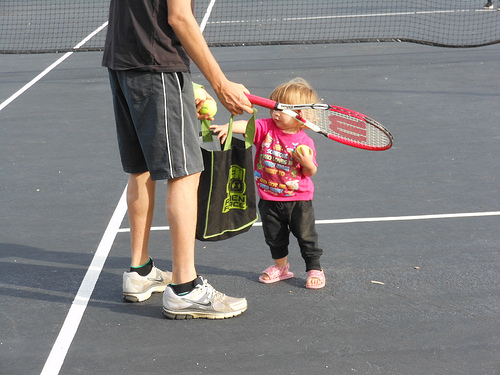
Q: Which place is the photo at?
A: It is at the field.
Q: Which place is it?
A: It is a field.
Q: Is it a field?
A: Yes, it is a field.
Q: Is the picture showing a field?
A: Yes, it is showing a field.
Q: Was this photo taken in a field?
A: Yes, it was taken in a field.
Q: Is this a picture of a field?
A: Yes, it is showing a field.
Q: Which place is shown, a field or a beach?
A: It is a field.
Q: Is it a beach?
A: No, it is a field.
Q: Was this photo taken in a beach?
A: No, the picture was taken in a field.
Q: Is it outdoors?
A: Yes, it is outdoors.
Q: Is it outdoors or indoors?
A: It is outdoors.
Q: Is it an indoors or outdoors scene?
A: It is outdoors.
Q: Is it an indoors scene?
A: No, it is outdoors.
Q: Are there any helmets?
A: No, there are no helmets.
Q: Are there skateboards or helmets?
A: No, there are no helmets or skateboards.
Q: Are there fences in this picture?
A: No, there are no fences.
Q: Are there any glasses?
A: No, there are no glasses.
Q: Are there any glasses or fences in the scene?
A: No, there are no glasses or fences.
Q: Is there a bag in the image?
A: Yes, there is a bag.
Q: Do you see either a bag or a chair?
A: Yes, there is a bag.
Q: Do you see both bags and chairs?
A: No, there is a bag but no chairs.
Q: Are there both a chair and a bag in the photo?
A: No, there is a bag but no chairs.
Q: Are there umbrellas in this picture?
A: No, there are no umbrellas.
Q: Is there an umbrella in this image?
A: No, there are no umbrellas.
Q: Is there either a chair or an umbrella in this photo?
A: No, there are no umbrellas or chairs.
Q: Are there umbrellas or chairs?
A: No, there are no umbrellas or chairs.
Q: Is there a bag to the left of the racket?
A: Yes, there is a bag to the left of the racket.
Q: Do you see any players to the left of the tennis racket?
A: No, there is a bag to the left of the tennis racket.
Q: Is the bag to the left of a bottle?
A: No, the bag is to the left of the tennis racket.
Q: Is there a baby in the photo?
A: Yes, there is a baby.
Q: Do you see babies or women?
A: Yes, there is a baby.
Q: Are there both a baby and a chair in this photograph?
A: No, there is a baby but no chairs.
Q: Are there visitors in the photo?
A: No, there are no visitors.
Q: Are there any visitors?
A: No, there are no visitors.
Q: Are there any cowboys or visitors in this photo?
A: No, there are no visitors or cowboys.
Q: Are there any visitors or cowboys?
A: No, there are no visitors or cowboys.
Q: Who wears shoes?
A: The baby wears shoes.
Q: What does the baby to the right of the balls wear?
A: The baby wears shoes.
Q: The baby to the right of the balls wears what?
A: The baby wears shoes.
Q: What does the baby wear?
A: The baby wears shoes.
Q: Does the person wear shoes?
A: Yes, the baby wears shoes.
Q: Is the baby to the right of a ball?
A: Yes, the baby is to the right of a ball.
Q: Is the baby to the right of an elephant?
A: No, the baby is to the right of a ball.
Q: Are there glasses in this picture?
A: No, there are no glasses.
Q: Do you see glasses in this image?
A: No, there are no glasses.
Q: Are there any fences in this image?
A: No, there are no fences.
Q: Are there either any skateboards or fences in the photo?
A: No, there are no fences or skateboards.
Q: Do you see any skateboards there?
A: No, there are no skateboards.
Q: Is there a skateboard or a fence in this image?
A: No, there are no skateboards or fences.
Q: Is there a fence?
A: No, there are no fences.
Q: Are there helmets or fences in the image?
A: No, there are no fences or helmets.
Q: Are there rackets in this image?
A: Yes, there is a racket.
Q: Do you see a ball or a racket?
A: Yes, there is a racket.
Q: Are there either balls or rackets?
A: Yes, there is a racket.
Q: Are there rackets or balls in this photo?
A: Yes, there is a racket.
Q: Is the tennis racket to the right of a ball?
A: Yes, the tennis racket is to the right of a ball.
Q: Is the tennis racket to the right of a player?
A: No, the tennis racket is to the right of a ball.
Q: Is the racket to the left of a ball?
A: No, the racket is to the right of a ball.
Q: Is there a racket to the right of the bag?
A: Yes, there is a racket to the right of the bag.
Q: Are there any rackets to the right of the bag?
A: Yes, there is a racket to the right of the bag.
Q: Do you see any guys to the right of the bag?
A: No, there is a racket to the right of the bag.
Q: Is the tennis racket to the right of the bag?
A: Yes, the tennis racket is to the right of the bag.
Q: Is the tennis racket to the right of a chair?
A: No, the tennis racket is to the right of the bag.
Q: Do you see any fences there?
A: No, there are no fences.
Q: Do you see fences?
A: No, there are no fences.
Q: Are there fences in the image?
A: No, there are no fences.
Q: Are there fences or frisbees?
A: No, there are no fences or frisbees.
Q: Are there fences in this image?
A: No, there are no fences.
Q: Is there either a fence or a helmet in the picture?
A: No, there are no fences or helmets.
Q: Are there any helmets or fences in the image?
A: No, there are no fences or helmets.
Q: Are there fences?
A: No, there are no fences.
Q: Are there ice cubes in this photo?
A: No, there are no ice cubes.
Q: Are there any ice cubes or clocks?
A: No, there are no ice cubes or clocks.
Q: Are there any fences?
A: No, there are no fences.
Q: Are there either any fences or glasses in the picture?
A: No, there are no fences or glasses.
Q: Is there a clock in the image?
A: No, there are no clocks.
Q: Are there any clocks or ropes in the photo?
A: No, there are no clocks or ropes.